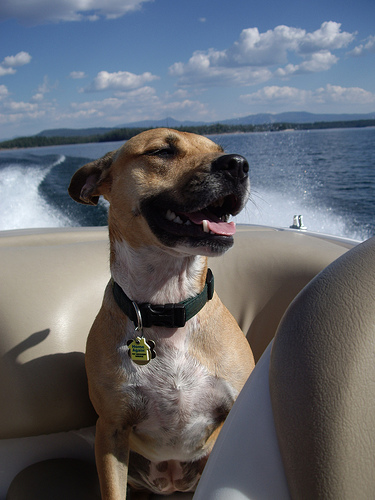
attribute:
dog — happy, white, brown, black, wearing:
[56, 96, 281, 461]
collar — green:
[71, 234, 245, 343]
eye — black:
[136, 121, 197, 169]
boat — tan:
[1, 140, 348, 409]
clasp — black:
[142, 282, 216, 333]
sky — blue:
[102, 13, 296, 98]